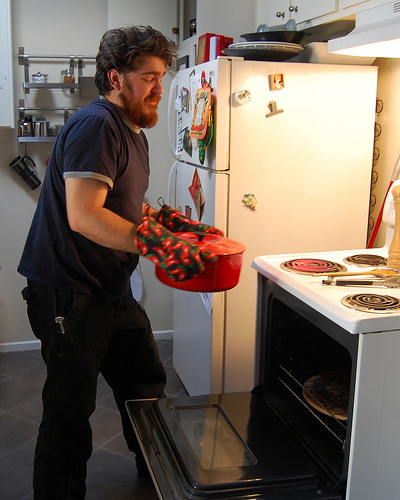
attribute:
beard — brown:
[127, 96, 158, 127]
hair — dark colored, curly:
[96, 25, 172, 94]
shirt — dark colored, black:
[16, 99, 152, 297]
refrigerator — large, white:
[163, 55, 381, 400]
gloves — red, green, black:
[134, 204, 223, 284]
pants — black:
[19, 277, 201, 500]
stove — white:
[123, 181, 398, 498]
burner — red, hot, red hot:
[281, 256, 346, 277]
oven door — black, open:
[125, 394, 348, 500]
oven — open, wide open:
[132, 230, 399, 491]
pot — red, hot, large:
[140, 209, 253, 296]